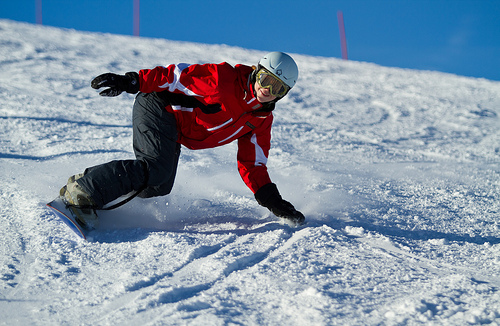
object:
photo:
[1, 1, 499, 325]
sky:
[2, 1, 499, 83]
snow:
[0, 21, 499, 325]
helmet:
[260, 51, 299, 87]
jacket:
[78, 62, 275, 205]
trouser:
[78, 92, 179, 214]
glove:
[91, 72, 130, 97]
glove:
[269, 200, 305, 225]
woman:
[58, 52, 307, 230]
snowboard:
[47, 191, 88, 242]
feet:
[63, 181, 98, 226]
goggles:
[256, 68, 288, 97]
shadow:
[310, 211, 499, 251]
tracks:
[121, 228, 299, 306]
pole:
[338, 11, 348, 61]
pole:
[133, 0, 140, 37]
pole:
[35, 2, 43, 25]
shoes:
[64, 178, 99, 226]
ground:
[2, 17, 499, 325]